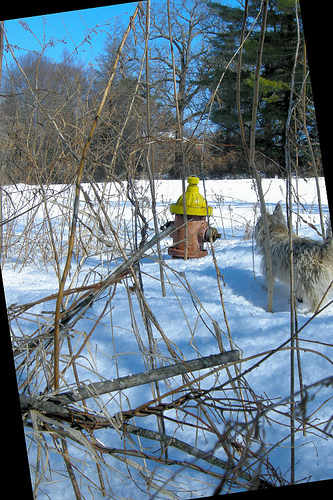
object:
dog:
[256, 200, 330, 317]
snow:
[1, 180, 331, 498]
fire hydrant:
[160, 175, 220, 263]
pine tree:
[194, 0, 318, 179]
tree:
[123, 0, 230, 180]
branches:
[1, 0, 331, 500]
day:
[0, 0, 332, 499]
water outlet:
[205, 226, 222, 243]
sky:
[1, 0, 332, 158]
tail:
[321, 215, 331, 256]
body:
[272, 233, 321, 295]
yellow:
[170, 176, 212, 216]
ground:
[1, 185, 331, 498]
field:
[1, 0, 331, 498]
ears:
[272, 199, 285, 217]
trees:
[309, 0, 330, 212]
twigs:
[0, 0, 331, 497]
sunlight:
[1, 0, 331, 499]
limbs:
[121, 0, 236, 181]